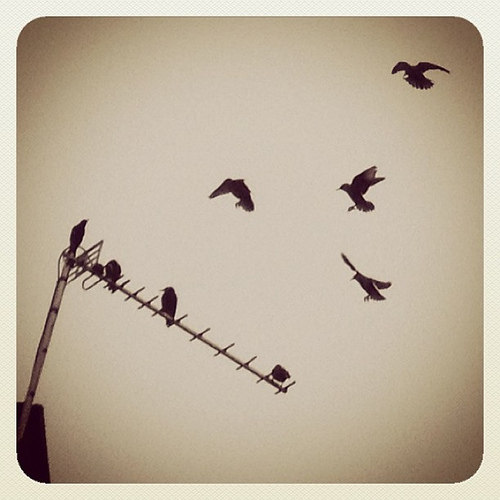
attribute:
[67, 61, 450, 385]
birds — black, up in the air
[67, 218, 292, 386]
birds — sitting together, perched on wire, resting, perched on pole, on top of thing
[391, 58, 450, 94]
bird — black, flying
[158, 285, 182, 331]
bird — black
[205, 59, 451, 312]
four birds — flying together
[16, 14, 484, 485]
sky — cloudless, white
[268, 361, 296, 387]
bird — sitting the lowest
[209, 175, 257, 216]
bird — flying, ready to land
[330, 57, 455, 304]
three birds — in the air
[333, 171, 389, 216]
feathers — tan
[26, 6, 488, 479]
photo — white